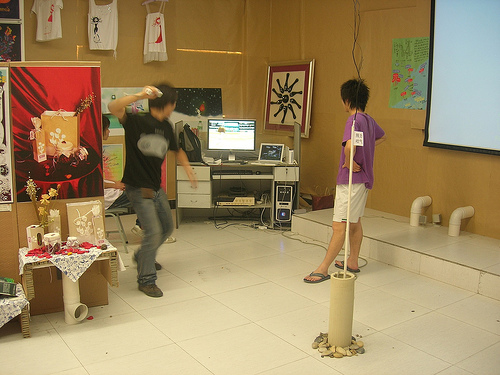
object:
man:
[302, 77, 389, 285]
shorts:
[331, 183, 370, 224]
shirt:
[334, 111, 387, 191]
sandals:
[303, 271, 332, 284]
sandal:
[332, 259, 362, 274]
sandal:
[302, 270, 331, 285]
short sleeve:
[340, 121, 360, 147]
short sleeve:
[373, 115, 386, 141]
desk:
[171, 145, 304, 234]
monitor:
[200, 117, 259, 165]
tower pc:
[274, 182, 294, 226]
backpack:
[177, 123, 210, 168]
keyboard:
[211, 168, 255, 176]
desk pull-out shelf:
[210, 168, 275, 184]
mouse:
[255, 170, 261, 175]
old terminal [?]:
[253, 139, 292, 169]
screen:
[207, 118, 257, 154]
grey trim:
[179, 127, 196, 154]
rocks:
[332, 352, 345, 359]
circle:
[325, 331, 355, 352]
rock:
[335, 346, 347, 356]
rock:
[318, 342, 328, 349]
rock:
[356, 347, 366, 355]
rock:
[312, 342, 322, 349]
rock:
[356, 340, 364, 348]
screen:
[422, 1, 499, 156]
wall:
[248, 0, 500, 243]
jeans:
[123, 179, 177, 283]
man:
[106, 79, 200, 299]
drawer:
[175, 164, 213, 184]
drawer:
[176, 180, 212, 197]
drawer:
[177, 193, 214, 210]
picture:
[260, 57, 318, 140]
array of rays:
[269, 71, 304, 125]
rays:
[280, 104, 289, 124]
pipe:
[409, 193, 436, 228]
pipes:
[444, 205, 475, 239]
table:
[17, 232, 126, 338]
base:
[58, 262, 91, 328]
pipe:
[60, 259, 89, 325]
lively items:
[64, 197, 109, 247]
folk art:
[307, 2, 375, 359]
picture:
[5, 65, 104, 207]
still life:
[7, 66, 107, 203]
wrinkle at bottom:
[417, 128, 499, 159]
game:
[202, 116, 297, 230]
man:
[102, 113, 183, 244]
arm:
[107, 84, 165, 122]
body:
[123, 110, 178, 299]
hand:
[340, 158, 362, 172]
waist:
[335, 157, 376, 175]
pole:
[342, 120, 355, 278]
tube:
[325, 268, 357, 349]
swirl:
[267, 73, 303, 125]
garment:
[139, 1, 173, 66]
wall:
[0, 1, 277, 225]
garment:
[84, 0, 119, 62]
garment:
[29, 0, 66, 44]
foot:
[302, 269, 329, 284]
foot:
[334, 259, 360, 272]